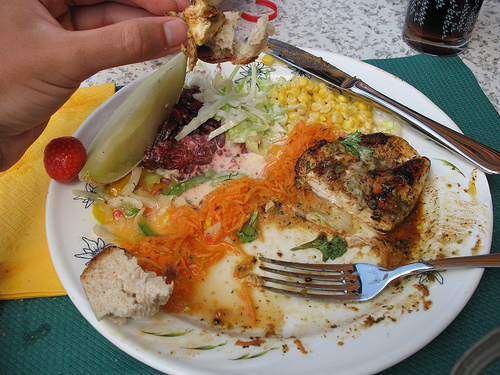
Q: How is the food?
A: Eaten.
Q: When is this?
A: Daytime.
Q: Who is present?
A: A person.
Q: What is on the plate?
A: Food.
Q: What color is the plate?
A: White.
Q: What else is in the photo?
A: Fork.